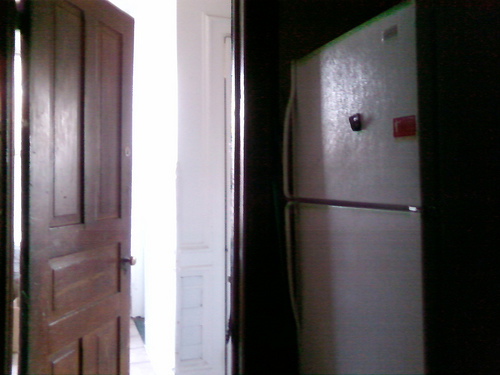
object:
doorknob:
[119, 253, 137, 267]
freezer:
[283, 0, 499, 373]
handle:
[281, 91, 295, 201]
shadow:
[276, 43, 334, 374]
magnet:
[347, 113, 364, 131]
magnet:
[392, 114, 416, 138]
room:
[0, 0, 499, 374]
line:
[291, 0, 419, 68]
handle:
[284, 199, 301, 332]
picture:
[0, 0, 499, 374]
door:
[177, 0, 230, 374]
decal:
[381, 24, 399, 41]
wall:
[246, 1, 281, 373]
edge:
[230, 0, 240, 374]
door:
[282, 0, 419, 207]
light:
[133, 156, 178, 257]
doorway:
[130, 0, 178, 374]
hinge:
[12, 4, 25, 30]